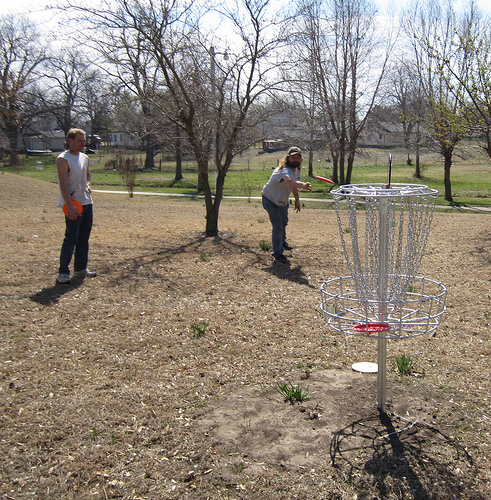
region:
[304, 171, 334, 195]
he threw the frisbee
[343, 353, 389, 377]
the frisbee is on the ground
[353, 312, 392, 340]
the frisbee is red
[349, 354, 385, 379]
the frisbee is white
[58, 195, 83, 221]
the man is holding the frisbee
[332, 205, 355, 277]
the chain is silver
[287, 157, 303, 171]
the man has a beard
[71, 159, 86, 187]
the shirt is white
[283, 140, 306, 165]
the man is wearing a hat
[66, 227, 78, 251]
the pants are blue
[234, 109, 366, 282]
person throwing a Frisbee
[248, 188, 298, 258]
person wearing blue jeans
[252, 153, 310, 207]
person wearing a t shirt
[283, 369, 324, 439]
weeds growing in the field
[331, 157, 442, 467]
frisbee holder in the ground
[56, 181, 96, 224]
holding an orange frisbee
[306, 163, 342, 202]
the frisbee is red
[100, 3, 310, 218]
the tree has no leaves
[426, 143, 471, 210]
the tree trunk is brown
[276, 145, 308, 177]
man is wearing a hat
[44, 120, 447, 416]
Men are playing with frisbees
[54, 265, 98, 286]
Man is wearing shoes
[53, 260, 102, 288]
Man is wearing white shoes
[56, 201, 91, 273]
Man is wearing pants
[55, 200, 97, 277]
Man is wearing blue pants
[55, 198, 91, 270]
Man is wearing jeans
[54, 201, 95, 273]
Man is wearing blue jeans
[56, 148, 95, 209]
Man is wearing a shirt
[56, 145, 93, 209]
Man is wearing a white shirt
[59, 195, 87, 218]
Man is holding a frisbee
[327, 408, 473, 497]
The shadow of the metal catcher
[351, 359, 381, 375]
A small white disk on the ground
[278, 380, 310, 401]
Green grass in the dirt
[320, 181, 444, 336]
A metal disk catcher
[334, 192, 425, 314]
Chains hanging down into container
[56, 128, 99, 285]
A man with an orange disk in his hand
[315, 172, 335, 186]
A red disk in the air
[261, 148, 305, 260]
A man wearing a hat, throwing a disk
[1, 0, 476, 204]
Several trees off in the grass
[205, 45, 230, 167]
A tall lamp post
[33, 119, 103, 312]
Guy standing holding a frisbee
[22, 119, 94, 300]
Guy standing holding an orange frisbee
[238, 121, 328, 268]
Guy with a hat throwing an orange frisbee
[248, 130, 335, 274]
Guy throwing an orange frisbee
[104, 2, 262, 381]
Dried tree standing in a brown field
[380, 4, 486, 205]
Dry tree with some yellow leaves standing in grass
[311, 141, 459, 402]
Large metal frisbee catcher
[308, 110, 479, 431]
Large metal frisbee catcher with orange frisbee in it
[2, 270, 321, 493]
Dried up brown field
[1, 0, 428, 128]
Many dried up tree branches on trees